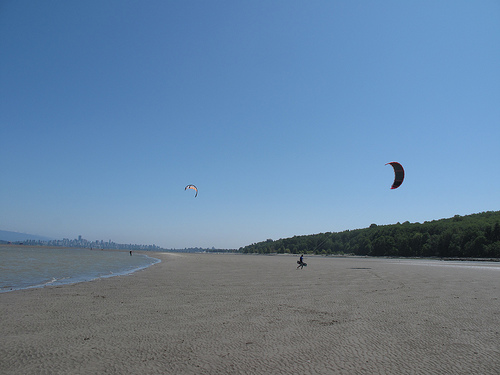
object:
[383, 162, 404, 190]
kite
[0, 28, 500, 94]
sky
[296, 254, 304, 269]
person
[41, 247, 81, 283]
water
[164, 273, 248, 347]
beach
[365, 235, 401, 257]
trees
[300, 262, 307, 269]
surboard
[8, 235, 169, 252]
city